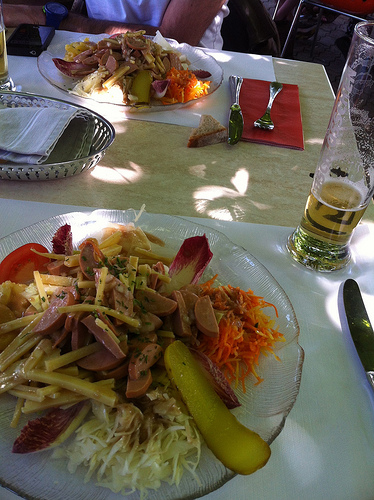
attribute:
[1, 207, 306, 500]
antipasto — elegant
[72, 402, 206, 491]
cheese — mozzarella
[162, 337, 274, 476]
pickle — sliced, green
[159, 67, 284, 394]
carrots — bright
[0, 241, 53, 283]
tomato — sliced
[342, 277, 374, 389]
knife — laying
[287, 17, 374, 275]
glass — tall, elongated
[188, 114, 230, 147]
bread — triangular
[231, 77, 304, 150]
napkin — folded, red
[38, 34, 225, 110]
plate — clear, round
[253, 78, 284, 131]
fork — silver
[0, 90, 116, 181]
basket — silver, metal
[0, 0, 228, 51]
person — sitting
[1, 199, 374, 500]
placemat — white